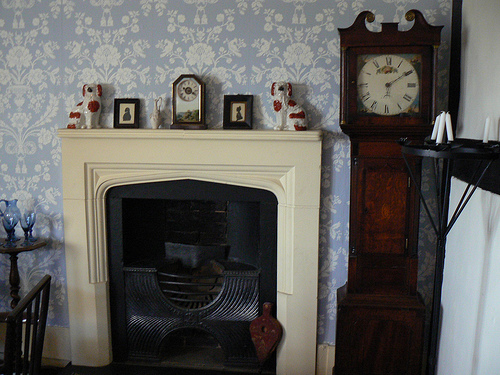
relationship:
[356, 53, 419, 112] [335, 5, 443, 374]
face of clock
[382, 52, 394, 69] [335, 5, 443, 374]
numerial ont he clock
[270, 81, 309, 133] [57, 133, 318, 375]
figurine on fireplace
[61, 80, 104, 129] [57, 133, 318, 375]
figurine on fireplace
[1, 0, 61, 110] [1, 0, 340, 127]
pattern on wall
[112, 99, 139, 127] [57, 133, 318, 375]
picture on fireplace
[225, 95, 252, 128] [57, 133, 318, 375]
picture on fireplace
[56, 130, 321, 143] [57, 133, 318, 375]
mantle on fireplace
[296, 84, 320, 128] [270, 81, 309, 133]
shadow of dog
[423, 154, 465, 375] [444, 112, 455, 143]
pole holding candle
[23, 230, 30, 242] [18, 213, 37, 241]
stem of glass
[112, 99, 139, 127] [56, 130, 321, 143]
picture on mantle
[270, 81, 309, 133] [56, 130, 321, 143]
figurine on mantle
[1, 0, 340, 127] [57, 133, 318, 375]
wall behind fireplace